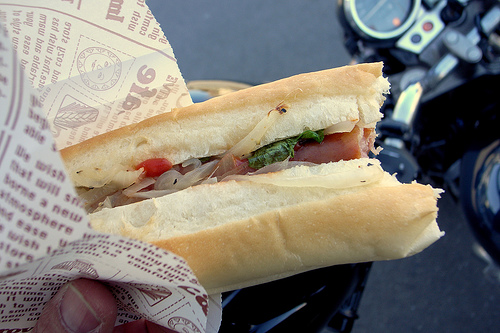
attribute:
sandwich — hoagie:
[46, 43, 455, 290]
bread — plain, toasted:
[51, 51, 460, 304]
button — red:
[420, 16, 443, 36]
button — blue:
[400, 29, 427, 46]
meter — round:
[327, 0, 434, 47]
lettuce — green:
[237, 121, 331, 173]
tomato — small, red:
[129, 144, 191, 183]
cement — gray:
[139, 3, 499, 328]